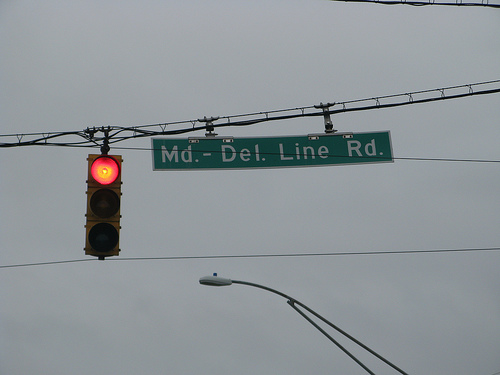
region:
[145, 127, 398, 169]
green street sign with white lettering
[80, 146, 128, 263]
red traffic signal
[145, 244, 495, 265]
power lines stretching across sky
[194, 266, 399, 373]
tall metal street lamp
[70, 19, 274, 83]
dark grey overcast sky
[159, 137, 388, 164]
words Md.-Del. Line Rd.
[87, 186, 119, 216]
yellow bulb not lit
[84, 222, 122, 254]
green bulb not lit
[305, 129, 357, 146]
brackets holding up street sign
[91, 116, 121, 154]
bracket holding up traffic signal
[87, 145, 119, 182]
The red traffic light.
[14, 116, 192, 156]
The wire the traffic light is hanging from.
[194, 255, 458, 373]
The street light with a blue light on top of it.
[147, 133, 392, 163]
The green street sign.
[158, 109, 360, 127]
The wires the green street sign is hanging from.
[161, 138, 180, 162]
The letter M on the street sign.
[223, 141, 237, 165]
The capital D on the street sign.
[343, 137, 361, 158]
The letter R on the street sign.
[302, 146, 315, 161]
The letter n on the street sign.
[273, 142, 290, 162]
The capital L on the street sign.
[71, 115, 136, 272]
traffic light suspended by cable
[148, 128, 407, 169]
sign in green with white letters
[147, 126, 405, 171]
sign identifying an east coast road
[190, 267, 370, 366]
streetlight in the background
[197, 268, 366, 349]
street light behind the traffic light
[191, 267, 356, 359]
street light behind the signal light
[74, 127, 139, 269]
traffic light indicating stop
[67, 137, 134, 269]
a red traffic light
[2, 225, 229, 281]
bottom cable for stability for the light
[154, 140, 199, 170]
an abbreviation for Maryland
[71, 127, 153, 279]
The traffic light is red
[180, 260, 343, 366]
The light is tall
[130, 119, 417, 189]
The street sign hangs from the line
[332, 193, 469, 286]
The sky is gray with no clouds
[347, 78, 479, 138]
This line is a power line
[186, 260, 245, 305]
The light is at the end of the pole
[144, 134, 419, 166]
The sign is green and white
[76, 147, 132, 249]
The red light is on top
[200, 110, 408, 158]
The clasps hold up the sign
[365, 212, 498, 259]
A power line runs across the sky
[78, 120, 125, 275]
traffic light is red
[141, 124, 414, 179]
street sign reads md. - del. line rd.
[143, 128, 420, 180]
street sign is green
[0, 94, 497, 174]
street sign hanging on cable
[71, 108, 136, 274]
traffic light hanging on cable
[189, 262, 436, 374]
street light in background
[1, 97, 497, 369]
sky looks overcast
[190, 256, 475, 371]
street light is long and thin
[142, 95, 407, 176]
street sign has 4 clips on top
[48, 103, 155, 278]
wire cable below traffic light